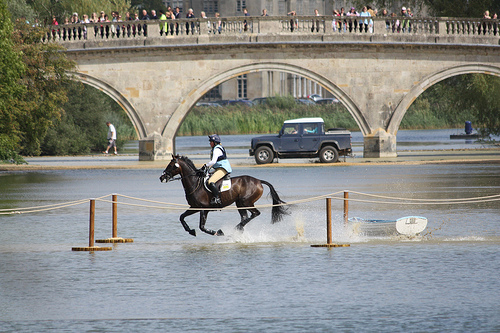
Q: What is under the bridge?
A: A vehicle.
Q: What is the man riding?
A: A horse.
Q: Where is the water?
A: Under the bridge.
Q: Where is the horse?
A: In water.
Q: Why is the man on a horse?
A: Riding it.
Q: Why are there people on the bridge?
A: Watching the horse.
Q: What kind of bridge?
A: Stone.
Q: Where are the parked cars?
A: Behind bridge.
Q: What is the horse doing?
A: Running on water.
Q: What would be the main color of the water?
A: Blue.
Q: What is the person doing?
A: Riding a horse.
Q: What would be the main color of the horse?
A: Brown.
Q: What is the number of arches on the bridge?
A: 3.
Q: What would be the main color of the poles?
A: Brown.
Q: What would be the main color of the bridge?
A: Grey.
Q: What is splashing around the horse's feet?
A: Water.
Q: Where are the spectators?
A: On the bridge.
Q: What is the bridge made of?
A: Concrete.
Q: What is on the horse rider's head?
A: Helmet.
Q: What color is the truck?
A: Blue and White.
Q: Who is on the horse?
A: A man.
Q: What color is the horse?
A: Brown.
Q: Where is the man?
A: On the horse.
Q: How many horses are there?
A: One.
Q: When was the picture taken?
A: In the daytime.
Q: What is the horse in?
A: Water.